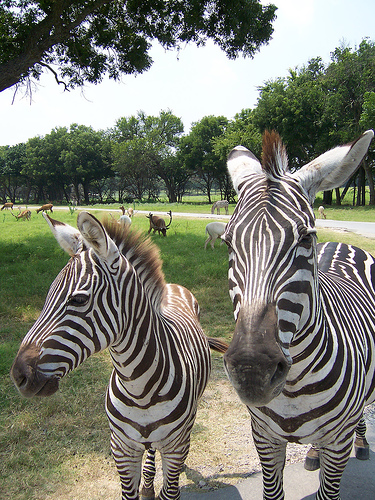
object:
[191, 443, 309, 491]
pebbles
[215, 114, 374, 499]
zebra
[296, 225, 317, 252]
eye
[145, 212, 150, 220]
antlers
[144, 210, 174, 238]
animals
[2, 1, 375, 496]
background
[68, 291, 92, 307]
eye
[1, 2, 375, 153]
sky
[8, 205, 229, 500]
zebra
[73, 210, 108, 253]
ear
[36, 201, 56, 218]
animal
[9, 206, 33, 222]
animal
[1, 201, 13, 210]
animal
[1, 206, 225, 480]
grass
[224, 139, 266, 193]
ear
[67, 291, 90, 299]
eyelashes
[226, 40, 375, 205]
trees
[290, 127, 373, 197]
ear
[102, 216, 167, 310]
mane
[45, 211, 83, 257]
ears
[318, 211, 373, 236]
road